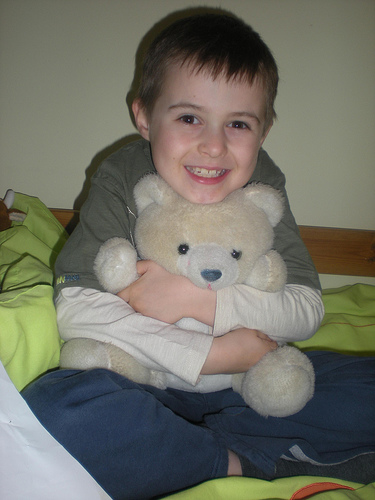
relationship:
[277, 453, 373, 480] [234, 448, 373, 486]
foot in sock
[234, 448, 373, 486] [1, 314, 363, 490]
sock under cover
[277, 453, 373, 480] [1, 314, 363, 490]
foot under cover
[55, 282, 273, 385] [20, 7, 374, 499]
arm of boy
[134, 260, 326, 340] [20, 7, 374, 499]
arm of boy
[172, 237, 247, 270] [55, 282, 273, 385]
bear in h arm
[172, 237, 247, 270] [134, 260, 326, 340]
bear in h arm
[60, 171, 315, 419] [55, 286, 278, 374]
bear in arm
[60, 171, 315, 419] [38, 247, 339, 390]
bear in arm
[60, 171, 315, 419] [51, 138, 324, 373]
bear in arms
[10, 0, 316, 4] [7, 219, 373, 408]
headboard from bed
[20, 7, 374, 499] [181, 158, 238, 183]
boy with smile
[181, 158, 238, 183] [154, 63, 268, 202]
smile on face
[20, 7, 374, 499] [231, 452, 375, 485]
boy with sock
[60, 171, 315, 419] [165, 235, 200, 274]
bear with eyes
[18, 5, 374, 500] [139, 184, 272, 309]
boy hugging bear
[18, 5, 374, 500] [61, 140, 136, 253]
boy wearing shirt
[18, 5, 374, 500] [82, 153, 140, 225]
boy wearing shirt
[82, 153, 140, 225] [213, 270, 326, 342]
shirt has sleeves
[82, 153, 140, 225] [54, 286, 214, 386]
shirt has sleeves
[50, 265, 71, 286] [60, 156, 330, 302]
logo on sleeves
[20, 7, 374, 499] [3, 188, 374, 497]
boy sitting bed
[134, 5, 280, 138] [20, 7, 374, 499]
brown hair of boy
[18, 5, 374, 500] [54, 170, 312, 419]
boy holding bear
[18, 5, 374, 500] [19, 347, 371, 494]
boy wearing pants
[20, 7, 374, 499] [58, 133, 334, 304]
boy wearing shirt